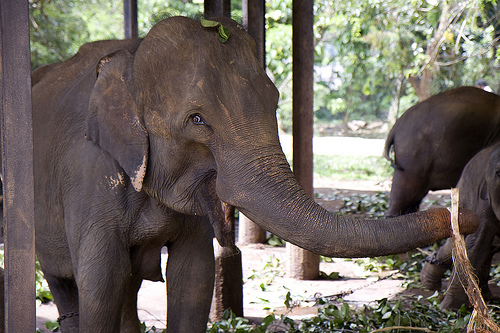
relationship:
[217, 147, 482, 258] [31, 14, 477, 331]
trunk of elephant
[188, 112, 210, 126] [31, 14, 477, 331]
right eye of elephant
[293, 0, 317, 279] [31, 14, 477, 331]
beam near elephant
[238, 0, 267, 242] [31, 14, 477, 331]
beam near elephant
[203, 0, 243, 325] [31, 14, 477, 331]
beam near elephant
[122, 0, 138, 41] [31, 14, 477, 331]
beam near elephant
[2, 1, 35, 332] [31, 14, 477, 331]
beam near elephant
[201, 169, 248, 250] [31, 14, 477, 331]
mouth of elephant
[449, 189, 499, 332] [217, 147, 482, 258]
hay in trunk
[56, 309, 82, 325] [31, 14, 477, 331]
chain on elephant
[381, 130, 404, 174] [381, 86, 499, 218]
tail of elephant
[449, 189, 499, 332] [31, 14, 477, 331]
hay being held by elephant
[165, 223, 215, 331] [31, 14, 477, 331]
front left leg of elephant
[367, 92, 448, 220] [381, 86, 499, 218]
back end of elephant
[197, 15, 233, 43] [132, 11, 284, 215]
leaves are on head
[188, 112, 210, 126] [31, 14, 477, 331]
right eye on elephant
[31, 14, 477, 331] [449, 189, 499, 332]
elephant holding hay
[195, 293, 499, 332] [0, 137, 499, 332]
leaves are on ground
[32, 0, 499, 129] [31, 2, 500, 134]
leaves are on trees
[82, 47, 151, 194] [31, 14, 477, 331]
ear on elephant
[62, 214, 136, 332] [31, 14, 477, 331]
leg on elephant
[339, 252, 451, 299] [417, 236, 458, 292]
chain on leg